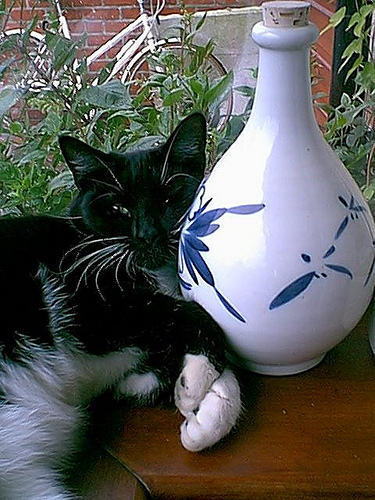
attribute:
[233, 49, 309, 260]
vase — blue, white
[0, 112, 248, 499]
cat — black, white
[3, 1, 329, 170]
wall — red, brick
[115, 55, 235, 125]
leaves — green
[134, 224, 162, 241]
nose — black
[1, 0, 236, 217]
plants — green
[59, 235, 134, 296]
whiskers — LONG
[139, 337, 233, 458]
paws — white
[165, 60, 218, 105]
leaves — green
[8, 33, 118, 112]
leaves — green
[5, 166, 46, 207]
leaves — green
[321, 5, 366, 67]
leaves — green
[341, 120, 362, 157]
leaves — green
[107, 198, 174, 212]
eyes — green